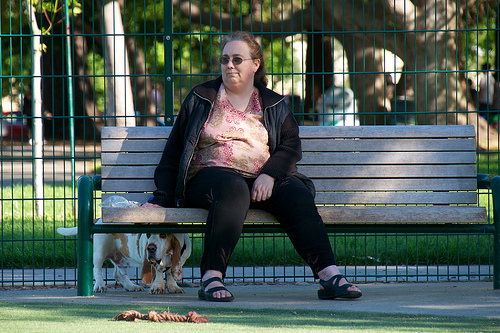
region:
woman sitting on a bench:
[66, 38, 498, 310]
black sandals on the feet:
[192, 273, 371, 303]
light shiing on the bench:
[348, 145, 421, 192]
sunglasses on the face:
[217, 52, 247, 66]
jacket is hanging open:
[157, 81, 310, 193]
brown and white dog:
[58, 203, 200, 295]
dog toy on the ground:
[115, 302, 211, 327]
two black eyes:
[144, 230, 168, 240]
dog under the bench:
[55, 213, 204, 303]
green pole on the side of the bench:
[65, 153, 114, 304]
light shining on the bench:
[97, 126, 122, 162]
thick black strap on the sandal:
[197, 273, 231, 285]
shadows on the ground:
[42, 286, 499, 331]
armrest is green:
[69, 165, 107, 203]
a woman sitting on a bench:
[158, 33, 357, 315]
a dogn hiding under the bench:
[68, 195, 190, 287]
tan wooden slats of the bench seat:
[317, 121, 486, 222]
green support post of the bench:
[62, 178, 94, 291]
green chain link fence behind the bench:
[1, 24, 93, 299]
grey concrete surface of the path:
[401, 285, 494, 314]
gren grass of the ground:
[11, 203, 64, 268]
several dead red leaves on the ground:
[108, 298, 208, 325]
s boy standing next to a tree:
[451, 48, 497, 139]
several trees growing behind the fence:
[11, 0, 473, 171]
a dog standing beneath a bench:
[53, 219, 194, 294]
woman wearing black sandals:
[196, 273, 362, 305]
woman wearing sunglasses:
[218, 55, 255, 67]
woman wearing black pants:
[188, 168, 338, 273]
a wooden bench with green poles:
[77, 125, 499, 298]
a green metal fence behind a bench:
[3, 2, 498, 283]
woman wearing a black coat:
[156, 78, 317, 201]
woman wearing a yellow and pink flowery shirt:
[191, 81, 272, 177]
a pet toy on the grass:
[117, 307, 206, 324]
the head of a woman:
[215, 28, 265, 98]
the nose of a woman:
[224, 54, 233, 71]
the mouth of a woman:
[223, 68, 241, 79]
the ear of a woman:
[250, 55, 262, 75]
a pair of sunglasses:
[213, 48, 263, 72]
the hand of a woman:
[246, 167, 275, 204]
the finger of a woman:
[263, 182, 275, 200]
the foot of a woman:
[196, 263, 237, 302]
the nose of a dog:
[144, 240, 159, 254]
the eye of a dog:
[156, 230, 169, 242]